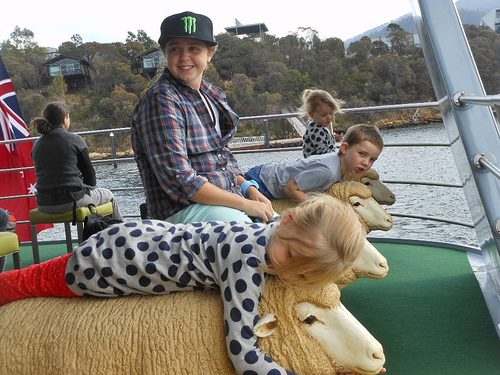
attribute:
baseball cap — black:
[159, 8, 214, 43]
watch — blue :
[235, 163, 265, 206]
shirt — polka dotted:
[78, 198, 353, 368]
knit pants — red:
[0, 190, 365, 302]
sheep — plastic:
[24, 225, 399, 373]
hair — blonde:
[249, 192, 369, 294]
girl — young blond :
[45, 187, 404, 343]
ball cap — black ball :
[135, 1, 245, 61]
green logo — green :
[171, 3, 203, 41]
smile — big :
[177, 64, 195, 73]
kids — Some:
[1, 6, 391, 371]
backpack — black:
[76, 207, 122, 244]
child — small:
[0, 196, 368, 373]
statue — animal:
[264, 180, 387, 227]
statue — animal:
[347, 233, 381, 294]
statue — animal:
[7, 284, 387, 374]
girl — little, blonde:
[4, 192, 374, 374]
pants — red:
[0, 242, 82, 305]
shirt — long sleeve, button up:
[128, 66, 245, 218]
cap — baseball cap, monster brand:
[156, 12, 218, 48]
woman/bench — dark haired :
[28, 101, 115, 221]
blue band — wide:
[236, 176, 259, 193]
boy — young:
[243, 120, 396, 197]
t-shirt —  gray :
[273, 157, 337, 178]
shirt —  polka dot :
[70, 216, 265, 301]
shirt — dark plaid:
[139, 72, 249, 202]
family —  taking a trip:
[1, 10, 385, 374]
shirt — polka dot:
[59, 218, 288, 373]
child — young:
[7, 186, 423, 372]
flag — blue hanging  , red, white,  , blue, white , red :
[0, 48, 57, 246]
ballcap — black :
[133, 4, 238, 66]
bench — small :
[17, 218, 84, 252]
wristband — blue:
[240, 176, 257, 192]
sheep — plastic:
[0, 285, 385, 372]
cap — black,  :
[150, 7, 226, 43]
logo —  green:
[183, 17, 197, 34]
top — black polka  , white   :
[85, 211, 297, 372]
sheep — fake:
[5, 235, 389, 374]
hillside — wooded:
[24, 41, 198, 137]